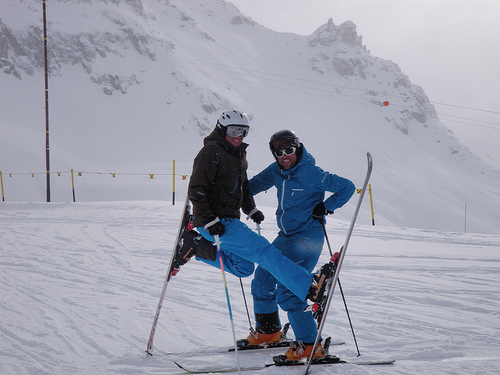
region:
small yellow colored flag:
[5, 170, 15, 177]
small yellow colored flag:
[28, 170, 35, 178]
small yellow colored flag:
[56, 170, 62, 177]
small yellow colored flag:
[74, 168, 86, 180]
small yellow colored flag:
[108, 170, 120, 180]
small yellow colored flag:
[178, 173, 188, 183]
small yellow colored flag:
[354, 187, 364, 197]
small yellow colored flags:
[7, 168, 67, 180]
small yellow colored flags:
[73, 168, 160, 182]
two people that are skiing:
[161, 95, 439, 355]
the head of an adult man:
[267, 126, 302, 176]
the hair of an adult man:
[265, 125, 299, 153]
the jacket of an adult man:
[244, 163, 348, 243]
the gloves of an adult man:
[305, 202, 336, 219]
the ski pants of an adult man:
[254, 232, 321, 313]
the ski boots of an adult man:
[238, 315, 318, 360]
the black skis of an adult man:
[224, 336, 304, 371]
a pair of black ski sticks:
[314, 221, 376, 336]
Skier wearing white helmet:
[200, 97, 256, 157]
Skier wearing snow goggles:
[205, 118, 255, 145]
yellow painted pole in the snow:
[61, 164, 84, 207]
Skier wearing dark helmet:
[265, 123, 307, 181]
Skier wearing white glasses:
[267, 138, 303, 161]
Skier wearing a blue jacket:
[253, 154, 363, 249]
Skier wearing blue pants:
[250, 223, 332, 343]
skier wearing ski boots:
[220, 316, 345, 371]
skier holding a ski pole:
[306, 196, 389, 362]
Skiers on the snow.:
[138, 104, 395, 369]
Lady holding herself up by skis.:
[136, 107, 377, 374]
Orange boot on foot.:
[280, 332, 326, 365]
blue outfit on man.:
[247, 124, 358, 351]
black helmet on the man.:
[267, 118, 307, 174]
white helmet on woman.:
[208, 105, 251, 154]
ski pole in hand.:
[209, 225, 253, 374]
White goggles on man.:
[262, 128, 307, 176]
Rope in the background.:
[0, 161, 198, 182]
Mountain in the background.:
[0, 5, 498, 237]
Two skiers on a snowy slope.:
[143, 108, 396, 372]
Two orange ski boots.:
[247, 327, 329, 362]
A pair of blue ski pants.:
[194, 213, 314, 303]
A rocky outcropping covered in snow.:
[298, 16, 473, 153]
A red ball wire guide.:
[381, 98, 391, 107]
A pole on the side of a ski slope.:
[40, 14, 50, 203]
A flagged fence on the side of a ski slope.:
[0, 160, 191, 206]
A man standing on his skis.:
[242, 130, 354, 365]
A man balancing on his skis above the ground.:
[173, 108, 333, 305]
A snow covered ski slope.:
[0, 199, 498, 374]